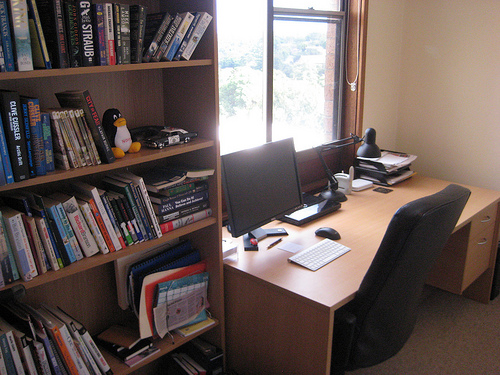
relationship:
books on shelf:
[0, 4, 211, 66] [0, 0, 240, 360]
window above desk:
[215, 6, 366, 143] [228, 160, 494, 374]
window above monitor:
[215, 6, 366, 143] [220, 140, 313, 235]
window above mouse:
[215, 6, 366, 143] [311, 226, 343, 242]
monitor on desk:
[220, 140, 313, 235] [228, 160, 494, 374]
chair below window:
[347, 191, 475, 361] [215, 6, 366, 143]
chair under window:
[347, 191, 475, 361] [215, 6, 366, 143]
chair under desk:
[347, 191, 475, 361] [228, 160, 494, 374]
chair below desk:
[347, 191, 475, 361] [228, 160, 494, 374]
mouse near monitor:
[311, 226, 343, 242] [220, 140, 313, 235]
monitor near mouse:
[220, 140, 313, 235] [311, 226, 343, 242]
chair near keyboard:
[347, 191, 475, 361] [288, 237, 353, 272]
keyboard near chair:
[288, 237, 353, 272] [347, 191, 475, 361]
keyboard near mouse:
[288, 237, 353, 272] [311, 226, 343, 242]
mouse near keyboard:
[311, 226, 343, 242] [288, 237, 353, 272]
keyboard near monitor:
[288, 237, 353, 272] [220, 140, 313, 235]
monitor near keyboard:
[220, 140, 313, 235] [288, 237, 353, 272]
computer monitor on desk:
[209, 136, 306, 255] [222, 159, 476, 369]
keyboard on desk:
[288, 237, 353, 272] [222, 159, 476, 369]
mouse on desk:
[311, 226, 343, 242] [222, 159, 476, 369]